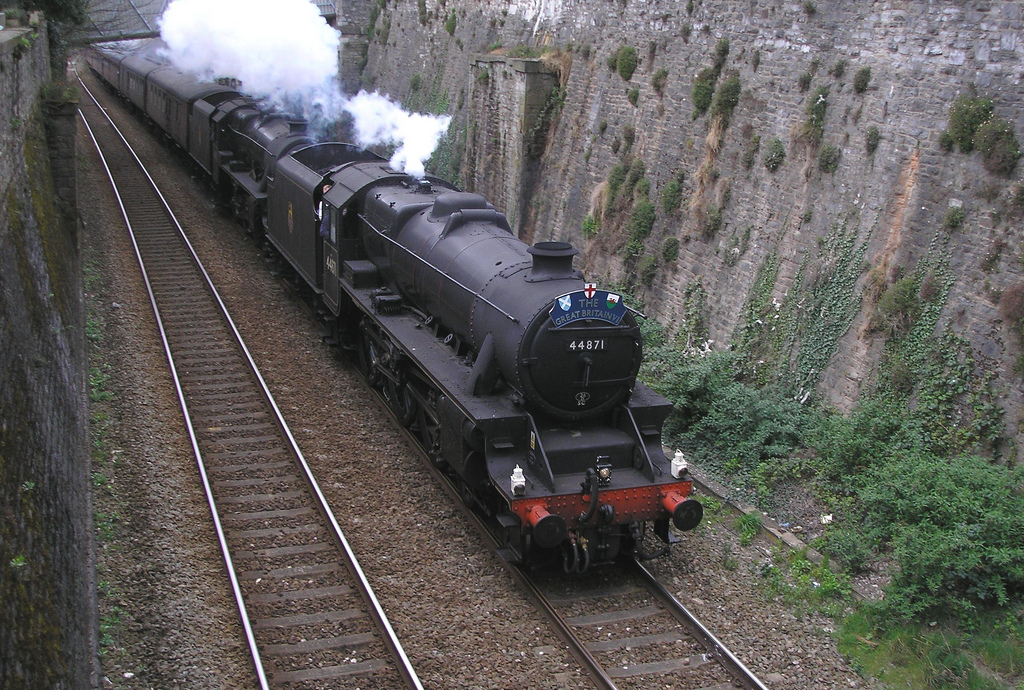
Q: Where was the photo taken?
A: On a railway.